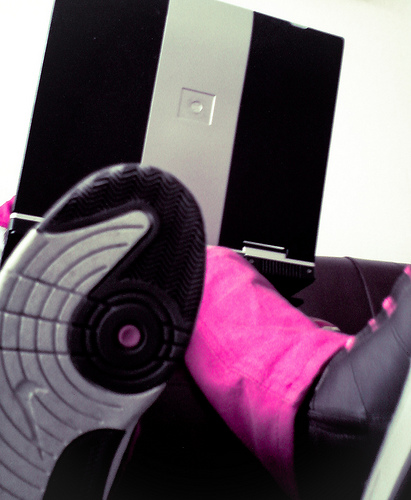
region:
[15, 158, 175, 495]
the bottom of a sneaker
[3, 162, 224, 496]
the sole of a shoe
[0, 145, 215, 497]
the rubber sole of a shoe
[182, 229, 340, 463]
a pink pant leg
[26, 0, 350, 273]
this is a laptop computer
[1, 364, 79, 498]
the Nike swoosh logo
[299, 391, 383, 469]
there is a zipper on the side of the shoe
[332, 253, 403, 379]
the shoe has pink laces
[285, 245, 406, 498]
the shoe is black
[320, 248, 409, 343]
the backrest of a leather sofa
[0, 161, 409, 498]
shoes are black, white, and pink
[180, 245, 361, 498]
person is wearing pink pants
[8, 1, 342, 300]
black and grey laptop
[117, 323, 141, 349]
pink circle on shoe sole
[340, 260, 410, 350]
pink laces on shoe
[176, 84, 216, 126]
square on back of laptop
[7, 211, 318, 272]
metal between clamshell pieces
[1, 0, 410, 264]
white wall behind couch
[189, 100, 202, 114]
circle inside square on laptop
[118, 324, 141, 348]
Pink circle on a shoe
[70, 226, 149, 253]
Small lines on the bottom of a shoe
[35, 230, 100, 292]
Small lines on the bottom of a shoe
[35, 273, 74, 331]
Small lines on the bottom of a shoe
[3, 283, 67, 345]
Small lines on the bottom of a shoe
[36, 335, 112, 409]
Small lines on the bottom of a shoe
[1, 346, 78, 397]
Small lines on the bottom of a shoe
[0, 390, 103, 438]
Small lines on the bottom of a shoe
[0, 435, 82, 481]
Small lines on the bottom of a shoe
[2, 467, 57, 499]
Small lines on the bottom of a shoe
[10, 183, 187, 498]
The bottom of the shoe.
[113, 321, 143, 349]
The dot is pink.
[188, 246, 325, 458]
The pants are pink.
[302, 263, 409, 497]
The shoes are black.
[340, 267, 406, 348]
The laces are pink.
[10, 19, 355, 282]
The computer is black and gray.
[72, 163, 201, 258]
The tip of the shoe is black.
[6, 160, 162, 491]
The bottom of the shoe is white.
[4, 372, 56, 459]
The logo is Nike.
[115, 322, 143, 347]
Pink circle on the bottom of a shoe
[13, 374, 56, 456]
Nike symbol on the bottom of a shoe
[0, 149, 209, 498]
Bottom of a nike shoe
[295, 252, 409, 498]
The side of a nike shoe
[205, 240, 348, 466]
Cuff of a pink pant leg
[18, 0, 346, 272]
The back or a black and silver laptop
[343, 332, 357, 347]
The side of a pink lace of a nike shoe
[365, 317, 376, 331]
The side of a pink lace of a nike shoe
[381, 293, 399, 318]
The side of a pink lace of a nike shoe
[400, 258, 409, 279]
The side of a pink lace of a nike shoe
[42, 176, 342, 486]
these are shoes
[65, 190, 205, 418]
the shoe is black and white and pink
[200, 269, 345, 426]
the pant leg is pink